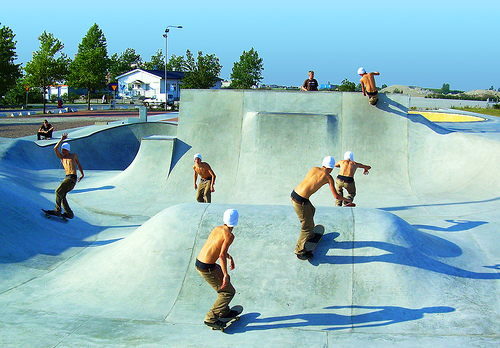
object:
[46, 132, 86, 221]
men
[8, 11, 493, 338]
park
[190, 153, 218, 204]
men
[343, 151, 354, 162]
hat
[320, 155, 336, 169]
hat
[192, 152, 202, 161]
hat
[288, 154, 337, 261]
man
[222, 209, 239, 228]
hat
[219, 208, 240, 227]
head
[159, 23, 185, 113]
street light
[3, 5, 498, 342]
picture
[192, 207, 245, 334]
man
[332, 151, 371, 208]
men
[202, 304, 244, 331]
skateboard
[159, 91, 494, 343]
course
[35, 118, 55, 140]
person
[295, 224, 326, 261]
skateboard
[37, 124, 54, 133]
shirt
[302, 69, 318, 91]
man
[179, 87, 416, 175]
ramp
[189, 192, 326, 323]
ramp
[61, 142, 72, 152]
caps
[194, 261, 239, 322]
pants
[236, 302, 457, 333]
shadow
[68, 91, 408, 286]
track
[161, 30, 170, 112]
pole